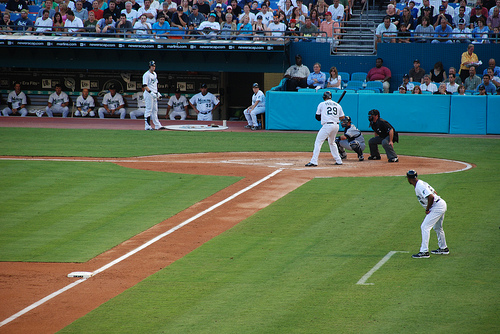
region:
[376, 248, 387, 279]
the line is white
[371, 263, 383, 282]
the line is white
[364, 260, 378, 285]
the line is white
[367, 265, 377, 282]
the line is white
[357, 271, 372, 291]
the line is white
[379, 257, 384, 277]
the line is white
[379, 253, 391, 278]
the line is white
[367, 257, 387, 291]
the line is white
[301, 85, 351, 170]
baseball player in a uniform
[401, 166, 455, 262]
baseball player in a uniform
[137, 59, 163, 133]
baseball player in a uniform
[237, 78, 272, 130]
baseball player in a uniform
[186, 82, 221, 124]
baseball player in a uniform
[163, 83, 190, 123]
baseball player in a uniform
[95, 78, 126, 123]
baseball player in a uniform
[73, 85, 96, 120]
baseball player in a uniform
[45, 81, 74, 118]
baseball player in a uniform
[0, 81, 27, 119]
baseball player in a uniform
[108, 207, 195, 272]
white line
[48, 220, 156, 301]
white line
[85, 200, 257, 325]
white line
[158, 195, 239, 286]
white line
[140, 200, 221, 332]
white line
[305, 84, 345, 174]
A batter at the plate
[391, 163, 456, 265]
The third base coach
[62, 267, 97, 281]
The third base pad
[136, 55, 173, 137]
A batter standing on deck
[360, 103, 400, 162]
An umpire crouched behind home plate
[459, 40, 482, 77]
A man in a yellow shirt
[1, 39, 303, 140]
A baseball bull pen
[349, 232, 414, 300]
White lines painted on the grass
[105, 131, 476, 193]
A circle of dirt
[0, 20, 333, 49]
Blue rails in front of the crowd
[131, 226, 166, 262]
white line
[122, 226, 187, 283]
white line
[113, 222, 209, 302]
white line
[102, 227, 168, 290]
white line